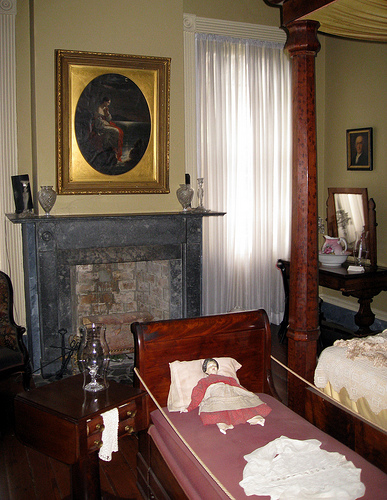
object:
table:
[274, 249, 386, 336]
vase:
[74, 317, 112, 402]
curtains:
[194, 33, 296, 318]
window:
[194, 27, 310, 328]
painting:
[76, 73, 151, 172]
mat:
[53, 50, 171, 193]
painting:
[345, 128, 375, 170]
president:
[351, 133, 366, 163]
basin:
[319, 253, 349, 267]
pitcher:
[320, 232, 348, 253]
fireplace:
[5, 209, 226, 379]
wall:
[2, 1, 387, 375]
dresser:
[13, 368, 149, 500]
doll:
[96, 95, 126, 164]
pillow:
[166, 356, 242, 411]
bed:
[128, 308, 384, 499]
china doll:
[179, 354, 270, 435]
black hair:
[199, 351, 216, 374]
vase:
[315, 232, 350, 272]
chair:
[0, 268, 33, 404]